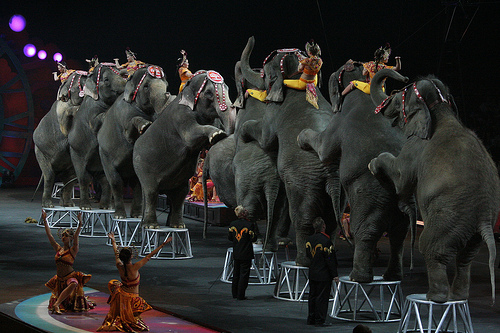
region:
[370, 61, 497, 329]
This is an elephant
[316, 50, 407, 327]
This is an elephant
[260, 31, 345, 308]
This is an elephant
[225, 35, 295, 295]
This is an elephant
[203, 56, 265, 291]
This is an elephant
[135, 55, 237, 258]
This is an elephant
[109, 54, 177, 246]
This is an elephant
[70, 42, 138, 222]
This is an elephant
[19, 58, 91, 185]
This is an elephant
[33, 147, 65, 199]
leg of an elephant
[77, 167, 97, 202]
leg of an elephant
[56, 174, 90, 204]
leg of an elephant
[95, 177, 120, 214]
leg of an elephant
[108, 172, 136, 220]
leg of an elephant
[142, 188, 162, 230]
leg of an elephant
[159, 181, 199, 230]
leg of an elephant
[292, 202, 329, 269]
leg of an elephant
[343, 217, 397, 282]
leg of an elephant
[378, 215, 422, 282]
leg of an elephant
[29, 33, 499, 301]
a bunch of elephants in a circus show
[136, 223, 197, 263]
a metal structure for the elephant to stand on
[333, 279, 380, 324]
triangular shaped beams to support the metal structure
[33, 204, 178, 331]
female circus performers posing on the floor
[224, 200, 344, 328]
male circus performers monitoring the elephants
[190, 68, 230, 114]
a red headdress on the elephant's head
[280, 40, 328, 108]
a woman riding on the back of the elephant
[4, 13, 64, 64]
purple lights near the ceiling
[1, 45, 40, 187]
a metal archway near the wall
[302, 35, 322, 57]
a headdress on the woman's head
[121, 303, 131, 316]
the skirt is orange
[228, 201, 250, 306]
the guy is standing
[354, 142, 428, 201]
elephant is leaning on the other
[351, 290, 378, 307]
the stool is gray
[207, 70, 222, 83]
the sign is red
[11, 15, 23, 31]
the light is purple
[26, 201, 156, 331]
showgirls at the circus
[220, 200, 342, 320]
elephant trainers on the ground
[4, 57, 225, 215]
elephant's leaning on each other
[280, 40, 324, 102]
person is riding the elephant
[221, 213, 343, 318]
trainers are wearing matching clothes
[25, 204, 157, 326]
show girls are wearing matching outfits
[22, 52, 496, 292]
elephants are performing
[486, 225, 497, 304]
elephant tail is hanging down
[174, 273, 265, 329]
shadows on the ground